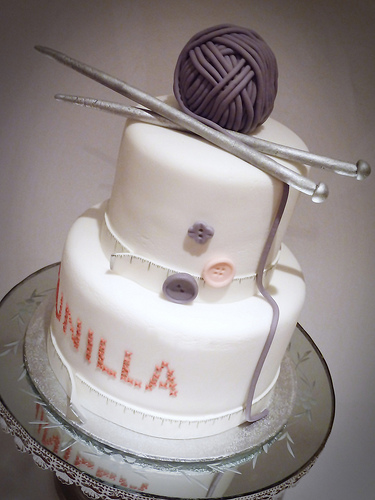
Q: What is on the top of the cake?
A: Knitting needles and yarn.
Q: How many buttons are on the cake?
A: Three.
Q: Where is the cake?
A: On a glass plate.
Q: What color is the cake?
A: White.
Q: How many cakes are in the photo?
A: One.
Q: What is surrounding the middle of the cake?
A: A measuring tape.